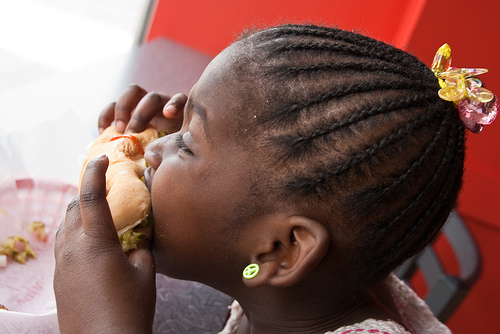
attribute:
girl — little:
[93, 16, 485, 289]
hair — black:
[270, 110, 341, 194]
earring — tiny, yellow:
[235, 260, 266, 290]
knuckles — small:
[70, 186, 108, 206]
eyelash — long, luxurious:
[167, 125, 191, 152]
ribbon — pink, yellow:
[434, 36, 498, 145]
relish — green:
[102, 219, 145, 259]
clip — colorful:
[428, 34, 493, 126]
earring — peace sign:
[237, 262, 264, 283]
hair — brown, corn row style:
[266, 22, 475, 272]